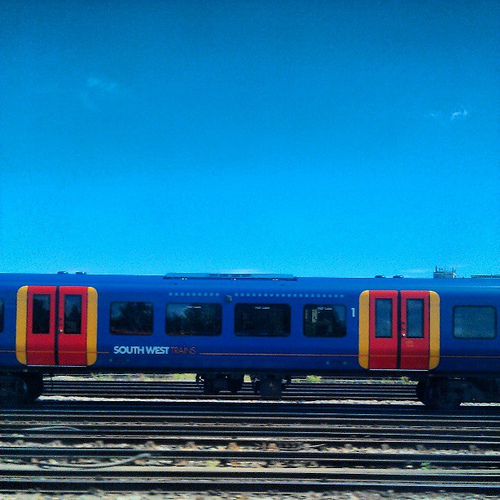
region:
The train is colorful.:
[3, 257, 498, 420]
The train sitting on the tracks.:
[1, 248, 499, 492]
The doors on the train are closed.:
[0, 259, 499, 401]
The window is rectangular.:
[104, 295, 160, 341]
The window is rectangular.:
[159, 295, 229, 339]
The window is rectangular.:
[227, 297, 299, 343]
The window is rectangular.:
[296, 293, 351, 344]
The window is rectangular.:
[448, 296, 499, 346]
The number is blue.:
[346, 298, 360, 323]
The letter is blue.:
[108, 340, 120, 357]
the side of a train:
[12, 265, 498, 373]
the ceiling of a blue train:
[100, 264, 132, 289]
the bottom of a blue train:
[125, 361, 167, 383]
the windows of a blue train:
[105, 293, 349, 338]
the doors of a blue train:
[27, 280, 91, 363]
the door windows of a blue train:
[30, 300, 84, 335]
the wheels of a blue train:
[402, 378, 461, 406]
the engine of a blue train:
[197, 365, 288, 410]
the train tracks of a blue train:
[83, 375, 182, 481]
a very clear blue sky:
[137, 112, 297, 216]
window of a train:
[468, 305, 491, 326]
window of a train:
[451, 314, 472, 340]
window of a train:
[407, 306, 422, 346]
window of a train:
[363, 297, 403, 340]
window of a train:
[302, 299, 343, 339]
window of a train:
[262, 304, 297, 339]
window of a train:
[232, 293, 268, 345]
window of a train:
[194, 298, 234, 340]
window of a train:
[111, 286, 173, 341]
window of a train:
[55, 276, 97, 344]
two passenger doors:
[359, 289, 441, 371]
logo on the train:
[113, 344, 196, 355]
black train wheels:
[0, 372, 41, 400]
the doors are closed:
[17, 283, 97, 365]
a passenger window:
[165, 302, 224, 335]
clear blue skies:
[5, 3, 497, 274]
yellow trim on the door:
[360, 290, 369, 367]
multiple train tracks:
[0, 375, 499, 493]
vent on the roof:
[164, 273, 295, 280]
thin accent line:
[200, 353, 357, 356]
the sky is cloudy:
[70, 61, 404, 298]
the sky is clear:
[62, 97, 452, 343]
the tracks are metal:
[106, 394, 221, 496]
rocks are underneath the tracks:
[53, 408, 125, 468]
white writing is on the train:
[103, 340, 313, 380]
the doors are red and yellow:
[335, 273, 499, 416]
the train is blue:
[92, 288, 297, 388]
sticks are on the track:
[31, 416, 88, 467]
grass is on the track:
[395, 442, 453, 477]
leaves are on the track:
[199, 434, 266, 467]